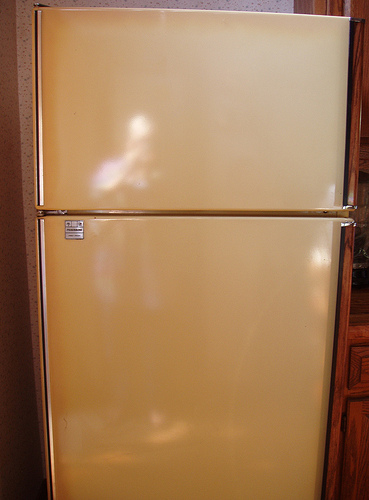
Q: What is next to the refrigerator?
A: Wood cabinets.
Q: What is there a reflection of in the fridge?
A: A man.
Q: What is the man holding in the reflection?
A: A camera.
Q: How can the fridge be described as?
A: An older model yellow fridge.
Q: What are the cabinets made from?
A: Wood.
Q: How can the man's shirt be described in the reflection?
A: It's blue.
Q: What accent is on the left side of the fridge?
A: A black and silver strip.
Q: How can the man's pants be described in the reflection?
A: As dark colored pants.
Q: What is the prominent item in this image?
A: A refrigerator in a kitchen.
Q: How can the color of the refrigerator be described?
A: Gold or yellow.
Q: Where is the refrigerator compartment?
A: On the bottom?.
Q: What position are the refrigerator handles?
A: On the right.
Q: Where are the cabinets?
A: To the right of the refrigerator.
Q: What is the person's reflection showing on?
A: A refrigerator.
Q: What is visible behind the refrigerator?
A: A white speckled wall.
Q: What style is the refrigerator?
A: Two doored.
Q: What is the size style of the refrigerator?
A: Full size.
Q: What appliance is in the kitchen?
A: Refrigerator.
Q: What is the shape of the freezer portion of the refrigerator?
A: Rectangular.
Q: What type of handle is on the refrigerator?
A: Wood.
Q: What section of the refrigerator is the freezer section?
A: Top.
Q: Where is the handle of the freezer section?
A: On the right of the freezer door.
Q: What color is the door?
A: Beige.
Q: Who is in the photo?
A: No one.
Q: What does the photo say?
A: Nothing.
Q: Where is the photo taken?
A: In a kitchen.